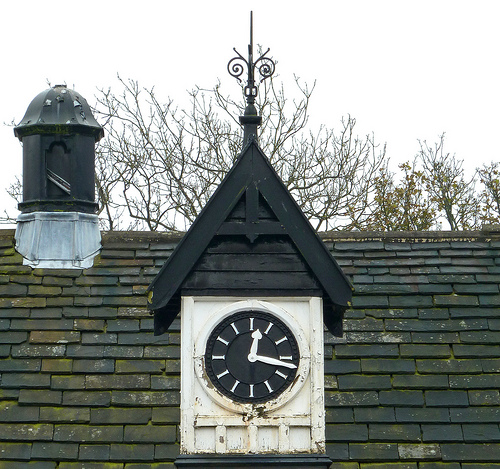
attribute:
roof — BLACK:
[372, 231, 474, 357]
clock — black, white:
[197, 300, 315, 421]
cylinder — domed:
[23, 195, 110, 265]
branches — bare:
[1, 34, 498, 245]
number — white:
[259, 373, 279, 402]